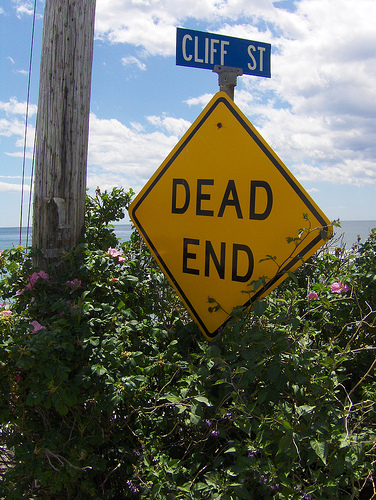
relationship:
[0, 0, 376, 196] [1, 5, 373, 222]
clouds in blue sky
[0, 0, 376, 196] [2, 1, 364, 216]
clouds in sky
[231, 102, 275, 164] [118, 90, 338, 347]
black border on sign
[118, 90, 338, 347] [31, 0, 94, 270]
sign on pole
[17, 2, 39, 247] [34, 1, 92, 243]
pole on pole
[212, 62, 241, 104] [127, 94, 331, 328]
pole by sign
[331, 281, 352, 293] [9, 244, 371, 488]
flowers in bushes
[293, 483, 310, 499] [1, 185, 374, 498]
flowers on bushes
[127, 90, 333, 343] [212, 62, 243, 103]
sign on pole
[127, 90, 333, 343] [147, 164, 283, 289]
sign says dead end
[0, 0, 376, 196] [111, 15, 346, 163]
clouds in sky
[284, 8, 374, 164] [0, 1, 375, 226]
clouds in blue sky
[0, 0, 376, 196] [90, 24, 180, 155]
clouds in sky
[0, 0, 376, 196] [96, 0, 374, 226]
clouds in sky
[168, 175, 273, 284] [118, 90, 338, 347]
dead end on sign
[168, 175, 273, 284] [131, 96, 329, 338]
dead end on border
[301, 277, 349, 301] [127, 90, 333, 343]
flowers near sign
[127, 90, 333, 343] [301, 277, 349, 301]
sign near flowers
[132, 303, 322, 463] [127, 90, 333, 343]
bush near sign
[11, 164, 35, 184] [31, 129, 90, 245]
wire running up side of utility pole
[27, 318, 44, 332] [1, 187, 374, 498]
flowers on bush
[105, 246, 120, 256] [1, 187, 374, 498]
flowers on bush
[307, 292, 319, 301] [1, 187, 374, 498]
flowers on bush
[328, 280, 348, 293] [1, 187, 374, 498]
flowers on bush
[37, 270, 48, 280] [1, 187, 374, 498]
flowers on bush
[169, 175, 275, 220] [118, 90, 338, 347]
letters on sign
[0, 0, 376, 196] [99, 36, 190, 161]
clouds in sky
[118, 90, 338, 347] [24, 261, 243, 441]
sign in bush